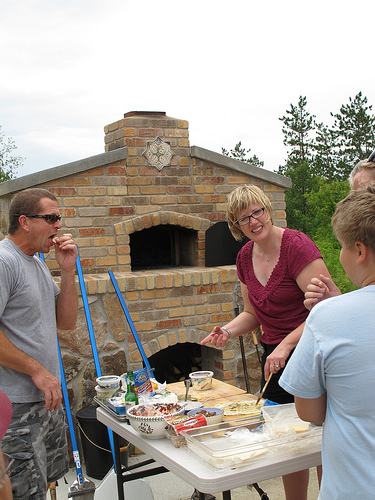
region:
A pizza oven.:
[9, 120, 283, 375]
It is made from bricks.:
[91, 153, 211, 295]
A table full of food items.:
[90, 363, 315, 475]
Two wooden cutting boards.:
[165, 368, 276, 416]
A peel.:
[86, 301, 150, 493]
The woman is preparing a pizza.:
[210, 180, 318, 417]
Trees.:
[280, 107, 327, 238]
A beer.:
[121, 369, 137, 421]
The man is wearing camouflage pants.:
[0, 392, 77, 494]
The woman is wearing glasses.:
[229, 202, 269, 228]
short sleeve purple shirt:
[228, 223, 326, 351]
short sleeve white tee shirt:
[275, 282, 373, 498]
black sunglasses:
[20, 204, 62, 225]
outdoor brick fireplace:
[3, 103, 294, 401]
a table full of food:
[93, 372, 324, 466]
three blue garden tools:
[33, 244, 156, 496]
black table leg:
[101, 430, 173, 494]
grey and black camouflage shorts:
[0, 390, 75, 496]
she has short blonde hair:
[219, 182, 279, 242]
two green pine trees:
[274, 89, 373, 171]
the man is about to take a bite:
[1, 188, 84, 496]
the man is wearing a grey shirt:
[0, 234, 66, 399]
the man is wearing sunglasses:
[21, 210, 63, 225]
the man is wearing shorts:
[4, 401, 68, 493]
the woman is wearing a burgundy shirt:
[233, 228, 323, 344]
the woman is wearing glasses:
[236, 203, 264, 226]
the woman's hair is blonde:
[226, 182, 275, 252]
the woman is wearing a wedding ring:
[273, 361, 279, 369]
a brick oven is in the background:
[0, 163, 286, 434]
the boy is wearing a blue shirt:
[290, 187, 373, 495]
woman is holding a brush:
[247, 353, 285, 412]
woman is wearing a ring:
[266, 361, 288, 371]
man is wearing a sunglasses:
[18, 207, 63, 224]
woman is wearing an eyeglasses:
[215, 203, 264, 230]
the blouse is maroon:
[222, 240, 326, 357]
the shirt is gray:
[2, 242, 77, 405]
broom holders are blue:
[62, 264, 162, 390]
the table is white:
[98, 405, 218, 497]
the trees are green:
[287, 135, 333, 230]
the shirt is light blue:
[302, 301, 373, 429]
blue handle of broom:
[77, 299, 106, 348]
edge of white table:
[187, 470, 230, 493]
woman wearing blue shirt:
[285, 292, 373, 498]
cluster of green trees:
[283, 110, 332, 169]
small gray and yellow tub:
[185, 370, 224, 391]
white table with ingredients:
[97, 376, 325, 487]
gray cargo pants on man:
[7, 397, 87, 493]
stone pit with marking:
[14, 108, 295, 269]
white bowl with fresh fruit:
[127, 398, 193, 433]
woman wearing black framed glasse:
[216, 197, 287, 225]